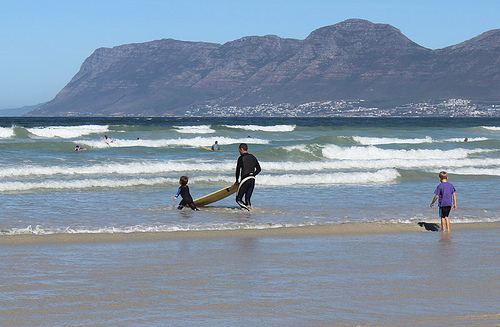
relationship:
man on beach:
[226, 138, 269, 212] [20, 194, 479, 326]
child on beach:
[419, 159, 488, 246] [20, 194, 479, 326]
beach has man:
[20, 194, 479, 326] [226, 138, 269, 212]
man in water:
[226, 138, 269, 212] [265, 119, 402, 187]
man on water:
[226, 138, 269, 212] [265, 119, 402, 187]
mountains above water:
[151, 26, 427, 91] [265, 119, 402, 187]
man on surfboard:
[226, 138, 269, 212] [198, 174, 237, 223]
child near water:
[419, 159, 488, 246] [265, 119, 402, 187]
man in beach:
[226, 138, 269, 212] [20, 194, 479, 326]